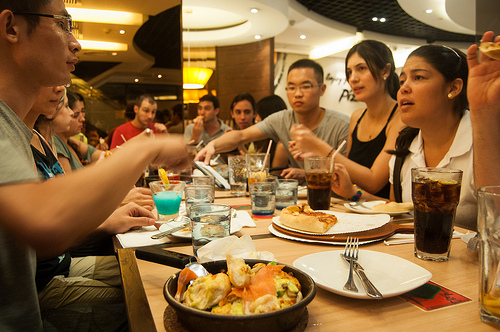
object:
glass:
[411, 166, 463, 261]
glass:
[476, 186, 500, 329]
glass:
[304, 149, 335, 211]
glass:
[188, 203, 232, 257]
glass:
[245, 153, 269, 188]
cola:
[411, 180, 461, 257]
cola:
[304, 171, 332, 211]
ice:
[411, 177, 458, 215]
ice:
[305, 168, 332, 189]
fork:
[344, 236, 361, 292]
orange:
[150, 167, 169, 186]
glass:
[148, 180, 184, 222]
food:
[180, 257, 297, 312]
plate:
[293, 225, 431, 299]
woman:
[286, 39, 405, 197]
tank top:
[345, 101, 398, 170]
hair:
[357, 39, 401, 100]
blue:
[152, 192, 181, 216]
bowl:
[161, 257, 316, 331]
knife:
[339, 252, 383, 299]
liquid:
[152, 193, 182, 215]